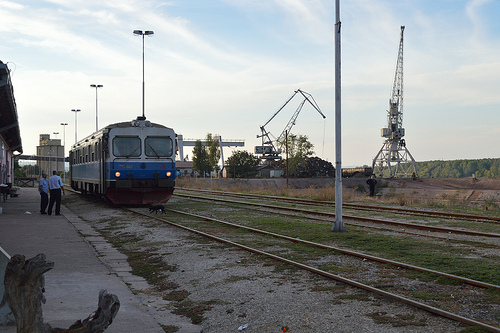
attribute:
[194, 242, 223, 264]
mark — black, spotted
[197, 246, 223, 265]
mark — black, spotted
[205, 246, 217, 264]
mark — spotted, black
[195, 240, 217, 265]
mark — black, spotted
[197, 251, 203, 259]
mark — black, spotted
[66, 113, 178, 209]
train — blue and white, commuter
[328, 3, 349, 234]
pole — tall, metal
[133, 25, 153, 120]
light — tall, overhead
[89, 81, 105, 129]
light — overhead, tall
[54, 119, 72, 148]
light — tall, overhead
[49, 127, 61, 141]
light — overhead, tall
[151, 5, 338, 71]
sky — clear and visible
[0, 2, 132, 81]
sky — clear and visible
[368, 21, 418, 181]
crane — large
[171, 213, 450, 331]
train tracks — metal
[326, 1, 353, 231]
pole — metal, light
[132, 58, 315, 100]
clouds — white, blue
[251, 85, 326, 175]
crane — large, bent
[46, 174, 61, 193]
shirt — blue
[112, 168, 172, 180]
train lights — on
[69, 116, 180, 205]
train — blue, white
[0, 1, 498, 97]
cloud — light, wispy